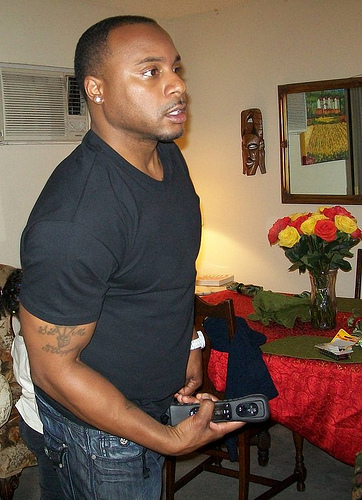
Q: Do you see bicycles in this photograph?
A: No, there are no bicycles.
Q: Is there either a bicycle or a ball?
A: No, there are no bicycles or balls.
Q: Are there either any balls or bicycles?
A: No, there are no bicycles or balls.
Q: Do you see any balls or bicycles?
A: No, there are no bicycles or balls.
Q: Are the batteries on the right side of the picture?
A: Yes, the batteries are on the right of the image.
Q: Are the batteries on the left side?
A: No, the batteries are on the right of the image.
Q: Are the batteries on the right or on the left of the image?
A: The batteries are on the right of the image.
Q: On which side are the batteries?
A: The batteries are on the right of the image.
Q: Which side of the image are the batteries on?
A: The batteries are on the right of the image.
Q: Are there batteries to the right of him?
A: Yes, there are batteries to the right of the man.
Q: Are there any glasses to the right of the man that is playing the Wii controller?
A: No, there are batteries to the right of the man.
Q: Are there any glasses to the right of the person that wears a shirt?
A: No, there are batteries to the right of the man.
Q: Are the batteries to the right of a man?
A: Yes, the batteries are to the right of a man.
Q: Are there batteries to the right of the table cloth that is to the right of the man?
A: Yes, there are batteries to the right of the table cloth.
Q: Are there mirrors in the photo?
A: Yes, there is a mirror.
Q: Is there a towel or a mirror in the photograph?
A: Yes, there is a mirror.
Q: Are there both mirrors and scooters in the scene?
A: No, there is a mirror but no scooters.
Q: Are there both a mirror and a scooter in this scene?
A: No, there is a mirror but no scooters.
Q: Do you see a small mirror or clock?
A: Yes, there is a small mirror.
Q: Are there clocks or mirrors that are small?
A: Yes, the mirror is small.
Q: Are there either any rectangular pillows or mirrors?
A: Yes, there is a rectangular mirror.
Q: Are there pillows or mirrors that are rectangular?
A: Yes, the mirror is rectangular.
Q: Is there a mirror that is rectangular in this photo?
A: Yes, there is a rectangular mirror.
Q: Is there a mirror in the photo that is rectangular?
A: Yes, there is a mirror that is rectangular.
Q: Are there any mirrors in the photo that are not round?
A: Yes, there is a rectangular mirror.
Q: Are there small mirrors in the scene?
A: Yes, there is a small mirror.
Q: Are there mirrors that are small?
A: Yes, there is a mirror that is small.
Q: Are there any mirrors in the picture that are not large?
A: Yes, there is a small mirror.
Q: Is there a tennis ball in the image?
A: No, there are no tennis balls.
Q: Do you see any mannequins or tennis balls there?
A: No, there are no tennis balls or mannequins.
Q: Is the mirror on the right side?
A: Yes, the mirror is on the right of the image.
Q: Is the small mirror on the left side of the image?
A: No, the mirror is on the right of the image.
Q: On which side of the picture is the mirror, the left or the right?
A: The mirror is on the right of the image.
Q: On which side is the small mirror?
A: The mirror is on the right of the image.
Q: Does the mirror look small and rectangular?
A: Yes, the mirror is small and rectangular.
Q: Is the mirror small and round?
A: No, the mirror is small but rectangular.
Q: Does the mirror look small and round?
A: No, the mirror is small but rectangular.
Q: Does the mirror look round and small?
A: No, the mirror is small but rectangular.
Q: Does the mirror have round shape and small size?
A: No, the mirror is small but rectangular.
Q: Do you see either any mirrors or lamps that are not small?
A: No, there is a mirror but it is small.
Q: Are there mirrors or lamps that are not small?
A: No, there is a mirror but it is small.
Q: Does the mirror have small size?
A: Yes, the mirror is small.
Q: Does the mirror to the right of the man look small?
A: Yes, the mirror is small.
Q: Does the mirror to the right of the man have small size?
A: Yes, the mirror is small.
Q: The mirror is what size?
A: The mirror is small.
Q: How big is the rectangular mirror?
A: The mirror is small.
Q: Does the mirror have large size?
A: No, the mirror is small.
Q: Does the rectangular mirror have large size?
A: No, the mirror is small.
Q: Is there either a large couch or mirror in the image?
A: No, there is a mirror but it is small.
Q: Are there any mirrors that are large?
A: No, there is a mirror but it is small.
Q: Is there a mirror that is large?
A: No, there is a mirror but it is small.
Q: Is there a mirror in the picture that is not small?
A: No, there is a mirror but it is small.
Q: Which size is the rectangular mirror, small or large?
A: The mirror is small.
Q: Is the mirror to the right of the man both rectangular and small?
A: Yes, the mirror is rectangular and small.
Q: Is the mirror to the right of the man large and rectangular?
A: No, the mirror is rectangular but small.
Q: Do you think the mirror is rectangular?
A: Yes, the mirror is rectangular.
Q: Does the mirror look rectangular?
A: Yes, the mirror is rectangular.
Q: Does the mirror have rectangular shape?
A: Yes, the mirror is rectangular.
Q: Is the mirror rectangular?
A: Yes, the mirror is rectangular.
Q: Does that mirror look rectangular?
A: Yes, the mirror is rectangular.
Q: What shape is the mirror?
A: The mirror is rectangular.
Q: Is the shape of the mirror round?
A: No, the mirror is rectangular.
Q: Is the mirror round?
A: No, the mirror is rectangular.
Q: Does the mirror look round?
A: No, the mirror is rectangular.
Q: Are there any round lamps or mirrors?
A: No, there is a mirror but it is rectangular.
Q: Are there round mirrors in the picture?
A: No, there is a mirror but it is rectangular.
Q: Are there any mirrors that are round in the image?
A: No, there is a mirror but it is rectangular.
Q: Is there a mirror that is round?
A: No, there is a mirror but it is rectangular.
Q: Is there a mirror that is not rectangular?
A: No, there is a mirror but it is rectangular.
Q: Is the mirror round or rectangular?
A: The mirror is rectangular.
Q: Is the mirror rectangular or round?
A: The mirror is rectangular.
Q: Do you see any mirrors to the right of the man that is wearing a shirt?
A: Yes, there is a mirror to the right of the man.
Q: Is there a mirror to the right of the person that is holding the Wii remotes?
A: Yes, there is a mirror to the right of the man.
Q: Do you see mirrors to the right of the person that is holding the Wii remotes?
A: Yes, there is a mirror to the right of the man.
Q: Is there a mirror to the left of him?
A: No, the mirror is to the right of the man.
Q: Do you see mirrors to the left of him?
A: No, the mirror is to the right of the man.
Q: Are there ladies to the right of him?
A: No, there is a mirror to the right of the man.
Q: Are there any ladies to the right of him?
A: No, there is a mirror to the right of the man.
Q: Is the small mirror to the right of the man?
A: Yes, the mirror is to the right of the man.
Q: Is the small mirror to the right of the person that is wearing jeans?
A: Yes, the mirror is to the right of the man.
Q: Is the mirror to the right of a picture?
A: No, the mirror is to the right of the man.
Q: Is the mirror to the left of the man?
A: No, the mirror is to the right of the man.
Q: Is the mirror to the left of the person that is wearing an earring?
A: No, the mirror is to the right of the man.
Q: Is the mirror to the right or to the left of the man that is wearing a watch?
A: The mirror is to the right of the man.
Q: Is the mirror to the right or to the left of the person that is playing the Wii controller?
A: The mirror is to the right of the man.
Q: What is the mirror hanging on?
A: The mirror is hanging on the wall.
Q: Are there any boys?
A: No, there are no boys.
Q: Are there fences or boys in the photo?
A: No, there are no boys or fences.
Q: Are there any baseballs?
A: No, there are no baseballs.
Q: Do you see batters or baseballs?
A: No, there are no baseballs or batters.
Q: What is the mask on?
A: The mask is on the wall.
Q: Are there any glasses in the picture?
A: No, there are no glasses.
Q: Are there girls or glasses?
A: No, there are no glasses or girls.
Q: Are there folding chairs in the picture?
A: No, there are no folding chairs.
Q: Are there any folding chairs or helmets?
A: No, there are no folding chairs or helmets.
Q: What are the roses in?
A: The roses are in the vase.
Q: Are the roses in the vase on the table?
A: Yes, the roses are in the vase.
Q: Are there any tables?
A: Yes, there is a table.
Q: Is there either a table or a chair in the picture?
A: Yes, there is a table.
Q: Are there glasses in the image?
A: No, there are no glasses.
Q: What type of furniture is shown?
A: The furniture is a table.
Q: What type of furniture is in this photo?
A: The furniture is a table.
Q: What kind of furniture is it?
A: The piece of furniture is a table.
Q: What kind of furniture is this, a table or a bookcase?
A: That is a table.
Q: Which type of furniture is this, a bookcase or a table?
A: That is a table.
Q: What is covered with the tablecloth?
A: The table is covered with the tablecloth.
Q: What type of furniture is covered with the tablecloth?
A: The piece of furniture is a table.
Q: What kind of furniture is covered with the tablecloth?
A: The piece of furniture is a table.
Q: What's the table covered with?
A: The table is covered with the tablecloth.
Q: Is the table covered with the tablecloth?
A: Yes, the table is covered with the tablecloth.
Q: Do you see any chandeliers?
A: No, there are no chandeliers.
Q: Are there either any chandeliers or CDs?
A: No, there are no chandeliers or cds.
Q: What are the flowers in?
A: The flowers are in the vase.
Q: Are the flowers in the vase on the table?
A: Yes, the flowers are in the vase.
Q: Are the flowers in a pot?
A: No, the flowers are in the vase.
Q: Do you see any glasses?
A: No, there are no glasses.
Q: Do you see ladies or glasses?
A: No, there are no glasses or ladies.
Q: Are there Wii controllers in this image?
A: Yes, there is a Wii controller.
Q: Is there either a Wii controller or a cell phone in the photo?
A: Yes, there is a Wii controller.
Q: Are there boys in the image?
A: No, there are no boys.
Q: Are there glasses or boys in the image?
A: No, there are no boys or glasses.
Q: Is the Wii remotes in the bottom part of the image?
A: Yes, the Wii remotes is in the bottom of the image.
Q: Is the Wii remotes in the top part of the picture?
A: No, the Wii remotes is in the bottom of the image.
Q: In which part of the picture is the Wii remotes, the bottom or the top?
A: The Wii remotes is in the bottom of the image.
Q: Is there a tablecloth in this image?
A: Yes, there is a tablecloth.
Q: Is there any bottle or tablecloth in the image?
A: Yes, there is a tablecloth.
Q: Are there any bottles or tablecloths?
A: Yes, there is a tablecloth.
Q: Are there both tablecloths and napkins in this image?
A: No, there is a tablecloth but no napkins.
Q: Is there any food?
A: No, there is no food.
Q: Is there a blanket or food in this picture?
A: No, there are no food or blankets.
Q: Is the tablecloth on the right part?
A: Yes, the tablecloth is on the right of the image.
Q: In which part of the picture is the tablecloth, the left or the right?
A: The tablecloth is on the right of the image.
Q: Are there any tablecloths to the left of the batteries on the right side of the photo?
A: Yes, there is a tablecloth to the left of the batteries.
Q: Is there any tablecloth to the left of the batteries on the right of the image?
A: Yes, there is a tablecloth to the left of the batteries.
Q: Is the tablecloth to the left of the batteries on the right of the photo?
A: Yes, the tablecloth is to the left of the batteries.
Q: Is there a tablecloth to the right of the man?
A: Yes, there is a tablecloth to the right of the man.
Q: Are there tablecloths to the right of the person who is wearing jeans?
A: Yes, there is a tablecloth to the right of the man.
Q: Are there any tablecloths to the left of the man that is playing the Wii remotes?
A: No, the tablecloth is to the right of the man.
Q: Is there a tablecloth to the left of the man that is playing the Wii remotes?
A: No, the tablecloth is to the right of the man.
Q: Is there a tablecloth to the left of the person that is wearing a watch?
A: No, the tablecloth is to the right of the man.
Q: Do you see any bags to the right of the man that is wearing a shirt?
A: No, there is a tablecloth to the right of the man.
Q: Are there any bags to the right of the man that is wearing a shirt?
A: No, there is a tablecloth to the right of the man.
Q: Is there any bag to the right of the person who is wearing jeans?
A: No, there is a tablecloth to the right of the man.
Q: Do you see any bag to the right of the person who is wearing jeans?
A: No, there is a tablecloth to the right of the man.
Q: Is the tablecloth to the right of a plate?
A: No, the tablecloth is to the right of a man.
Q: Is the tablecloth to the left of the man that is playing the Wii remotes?
A: No, the tablecloth is to the right of the man.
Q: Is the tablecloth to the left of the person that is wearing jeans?
A: No, the tablecloth is to the right of the man.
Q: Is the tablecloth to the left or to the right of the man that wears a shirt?
A: The tablecloth is to the right of the man.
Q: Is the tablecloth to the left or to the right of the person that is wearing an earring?
A: The tablecloth is to the right of the man.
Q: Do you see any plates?
A: No, there are no plates.